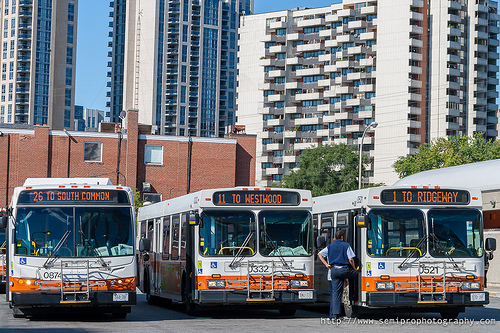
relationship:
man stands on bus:
[320, 219, 360, 305] [299, 184, 488, 325]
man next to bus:
[320, 219, 360, 305] [299, 184, 488, 325]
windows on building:
[82, 133, 171, 176] [9, 112, 259, 196]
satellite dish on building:
[107, 112, 130, 123] [9, 112, 259, 196]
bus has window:
[8, 177, 135, 311] [16, 205, 137, 256]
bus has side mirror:
[299, 184, 488, 325] [480, 221, 499, 260]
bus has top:
[8, 177, 135, 311] [15, 167, 126, 184]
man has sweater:
[320, 219, 360, 305] [328, 242, 353, 270]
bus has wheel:
[299, 184, 488, 325] [440, 240, 470, 256]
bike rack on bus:
[63, 259, 85, 309] [8, 177, 135, 311]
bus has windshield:
[8, 177, 135, 311] [20, 206, 128, 266]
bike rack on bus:
[63, 259, 85, 309] [311, 184, 489, 320]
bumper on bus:
[7, 288, 137, 305] [8, 177, 135, 311]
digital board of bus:
[26, 189, 116, 201] [8, 177, 135, 311]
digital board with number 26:
[26, 189, 116, 201] [32, 191, 44, 203]